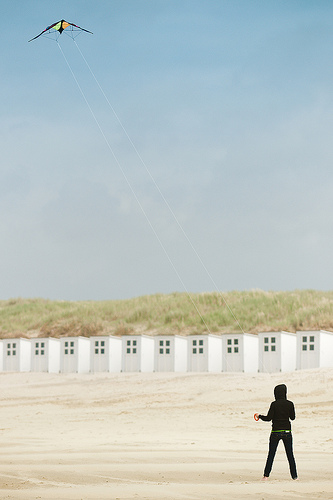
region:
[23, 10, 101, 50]
kite in the sky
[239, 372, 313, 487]
woman flying a kite on sand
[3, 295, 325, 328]
green grass on a hill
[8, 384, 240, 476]
tan sand at a beach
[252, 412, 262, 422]
handle of kite in woman's hand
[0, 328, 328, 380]
white buildings on a beach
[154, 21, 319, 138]
blue sky in the background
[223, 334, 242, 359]
windows of a building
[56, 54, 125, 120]
string of a kite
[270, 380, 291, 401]
black hood on a woman's head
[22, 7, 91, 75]
the kite is flying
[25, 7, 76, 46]
the kite is flying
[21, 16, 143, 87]
the kite is flying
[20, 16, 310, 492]
Person flying a kite.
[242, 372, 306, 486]
Person dressed all in black.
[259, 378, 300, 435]
Long sleeve jacket.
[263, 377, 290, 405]
Hood on jacket.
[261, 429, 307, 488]
A pair of black pants.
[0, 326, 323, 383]
A row of small buildings.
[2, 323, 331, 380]
The buildings all have four small windows each.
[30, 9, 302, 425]
Two strings attached to kite.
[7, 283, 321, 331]
Hill with green and brown grass.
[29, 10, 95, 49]
Black kite with orange and yellow.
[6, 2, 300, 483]
a person is flying a kite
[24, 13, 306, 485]
someone flies a kite at the beach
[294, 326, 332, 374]
small white shed in the background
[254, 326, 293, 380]
small white shed in the background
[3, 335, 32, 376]
small white shed in the background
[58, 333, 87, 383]
small white shed in the background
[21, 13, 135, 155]
a colorful kite has two strings attached to it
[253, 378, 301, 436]
someone is wearing a black hooded jacket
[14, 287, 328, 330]
a patch of grass on a hill in the background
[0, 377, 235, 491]
an expanse of golden colored sand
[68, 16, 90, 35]
black wings on kite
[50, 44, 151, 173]
white strings holding up kite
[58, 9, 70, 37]
orange section of kite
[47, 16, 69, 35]
green color on kite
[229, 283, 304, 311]
brown grass on the hill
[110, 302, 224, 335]
green grass spread over the hill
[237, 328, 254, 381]
edge of square white building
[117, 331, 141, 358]
small windows in white building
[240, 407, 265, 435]
red and white round disc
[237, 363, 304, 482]
woman standing on sand